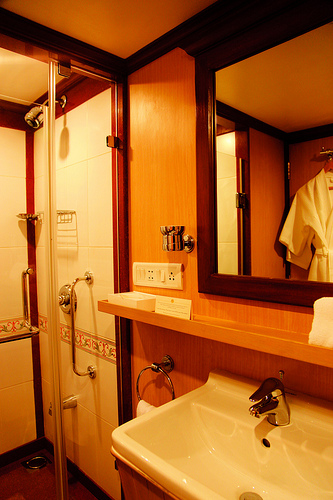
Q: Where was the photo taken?
A: It was taken at the bathroom.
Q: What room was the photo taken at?
A: It was taken at the bathroom.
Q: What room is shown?
A: It is a bathroom.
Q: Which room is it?
A: It is a bathroom.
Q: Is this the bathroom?
A: Yes, it is the bathroom.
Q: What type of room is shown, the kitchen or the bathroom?
A: It is the bathroom.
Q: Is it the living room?
A: No, it is the bathroom.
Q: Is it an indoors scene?
A: Yes, it is indoors.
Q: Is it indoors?
A: Yes, it is indoors.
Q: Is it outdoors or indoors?
A: It is indoors.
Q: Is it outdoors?
A: No, it is indoors.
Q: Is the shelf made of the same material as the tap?
A: No, the shelf is made of wood and the tap is made of metal.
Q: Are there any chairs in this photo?
A: No, there are no chairs.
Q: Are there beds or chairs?
A: No, there are no chairs or beds.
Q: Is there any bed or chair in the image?
A: No, there are no chairs or beds.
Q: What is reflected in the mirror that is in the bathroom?
A: The robe is reflected in the mirror.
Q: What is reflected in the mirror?
A: The robe is reflected in the mirror.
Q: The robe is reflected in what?
A: The robe is reflected in the mirror.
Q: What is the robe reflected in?
A: The robe is reflected in the mirror.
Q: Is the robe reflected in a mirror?
A: Yes, the robe is reflected in a mirror.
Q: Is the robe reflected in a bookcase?
A: No, the robe is reflected in a mirror.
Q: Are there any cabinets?
A: No, there are no cabinets.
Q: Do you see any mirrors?
A: Yes, there is a mirror.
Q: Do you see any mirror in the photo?
A: Yes, there is a mirror.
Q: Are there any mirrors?
A: Yes, there is a mirror.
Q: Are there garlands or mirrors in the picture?
A: Yes, there is a mirror.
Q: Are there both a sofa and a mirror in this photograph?
A: No, there is a mirror but no sofas.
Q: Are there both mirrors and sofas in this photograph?
A: No, there is a mirror but no sofas.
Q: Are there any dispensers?
A: No, there are no dispensers.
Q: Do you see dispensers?
A: No, there are no dispensers.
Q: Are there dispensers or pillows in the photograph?
A: No, there are no dispensers or pillows.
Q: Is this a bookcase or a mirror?
A: This is a mirror.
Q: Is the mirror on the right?
A: Yes, the mirror is on the right of the image.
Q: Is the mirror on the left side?
A: No, the mirror is on the right of the image.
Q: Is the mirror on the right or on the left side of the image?
A: The mirror is on the right of the image.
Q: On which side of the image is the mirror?
A: The mirror is on the right of the image.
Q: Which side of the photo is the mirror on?
A: The mirror is on the right of the image.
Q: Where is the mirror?
A: The mirror is in the bathroom.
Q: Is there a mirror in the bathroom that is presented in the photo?
A: Yes, there is a mirror in the bathroom.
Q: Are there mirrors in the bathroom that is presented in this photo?
A: Yes, there is a mirror in the bathroom.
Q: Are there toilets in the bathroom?
A: No, there is a mirror in the bathroom.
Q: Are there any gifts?
A: No, there are no gifts.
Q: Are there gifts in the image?
A: No, there are no gifts.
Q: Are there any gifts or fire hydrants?
A: No, there are no gifts or fire hydrants.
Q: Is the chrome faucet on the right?
A: Yes, the faucet is on the right of the image.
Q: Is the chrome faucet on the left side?
A: No, the tap is on the right of the image.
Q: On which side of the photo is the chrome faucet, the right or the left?
A: The faucet is on the right of the image.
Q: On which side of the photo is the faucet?
A: The faucet is on the right of the image.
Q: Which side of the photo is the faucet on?
A: The faucet is on the right of the image.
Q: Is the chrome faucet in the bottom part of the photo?
A: Yes, the faucet is in the bottom of the image.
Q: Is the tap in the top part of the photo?
A: No, the tap is in the bottom of the image.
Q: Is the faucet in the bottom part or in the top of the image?
A: The faucet is in the bottom of the image.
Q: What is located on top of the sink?
A: The tap is on top of the sink.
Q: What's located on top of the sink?
A: The tap is on top of the sink.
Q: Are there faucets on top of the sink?
A: Yes, there is a faucet on top of the sink.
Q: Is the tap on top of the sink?
A: Yes, the tap is on top of the sink.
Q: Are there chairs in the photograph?
A: No, there are no chairs.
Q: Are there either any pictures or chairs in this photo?
A: No, there are no chairs or pictures.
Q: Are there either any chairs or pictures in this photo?
A: No, there are no chairs or pictures.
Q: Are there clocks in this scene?
A: No, there are no clocks.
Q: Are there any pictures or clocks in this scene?
A: No, there are no clocks or pictures.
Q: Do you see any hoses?
A: No, there are no hoses.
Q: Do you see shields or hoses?
A: No, there are no hoses or shields.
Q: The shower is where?
A: The shower is in the bathroom.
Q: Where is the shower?
A: The shower is in the bathroom.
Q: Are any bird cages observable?
A: No, there are no bird cages.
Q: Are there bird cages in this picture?
A: No, there are no bird cages.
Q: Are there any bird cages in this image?
A: No, there are no bird cages.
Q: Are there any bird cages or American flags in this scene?
A: No, there are no bird cages or American flags.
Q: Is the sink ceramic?
A: Yes, the sink is ceramic.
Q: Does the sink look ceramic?
A: Yes, the sink is ceramic.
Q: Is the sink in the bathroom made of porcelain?
A: Yes, the sink is made of porcelain.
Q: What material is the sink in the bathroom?
A: The sink is made of porcelain.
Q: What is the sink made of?
A: The sink is made of porcelain.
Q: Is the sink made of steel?
A: No, the sink is made of porcelain.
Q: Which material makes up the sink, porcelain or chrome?
A: The sink is made of porcelain.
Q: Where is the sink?
A: The sink is in the bathroom.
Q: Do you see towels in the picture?
A: Yes, there is a towel.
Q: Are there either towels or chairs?
A: Yes, there is a towel.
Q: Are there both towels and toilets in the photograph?
A: No, there is a towel but no toilets.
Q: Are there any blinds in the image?
A: No, there are no blinds.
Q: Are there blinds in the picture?
A: No, there are no blinds.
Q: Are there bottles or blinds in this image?
A: No, there are no blinds or bottles.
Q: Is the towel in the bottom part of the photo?
A: Yes, the towel is in the bottom of the image.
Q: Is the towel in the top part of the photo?
A: No, the towel is in the bottom of the image.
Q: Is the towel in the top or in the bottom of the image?
A: The towel is in the bottom of the image.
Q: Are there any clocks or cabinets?
A: No, there are no cabinets or clocks.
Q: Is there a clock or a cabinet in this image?
A: No, there are no cabinets or clocks.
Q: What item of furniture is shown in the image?
A: The piece of furniture is a shelf.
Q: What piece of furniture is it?
A: The piece of furniture is a shelf.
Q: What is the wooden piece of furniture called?
A: The piece of furniture is a shelf.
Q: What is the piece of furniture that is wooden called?
A: The piece of furniture is a shelf.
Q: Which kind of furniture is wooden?
A: The furniture is a shelf.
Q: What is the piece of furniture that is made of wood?
A: The piece of furniture is a shelf.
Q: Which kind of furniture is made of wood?
A: The furniture is a shelf.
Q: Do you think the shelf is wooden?
A: Yes, the shelf is wooden.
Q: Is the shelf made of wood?
A: Yes, the shelf is made of wood.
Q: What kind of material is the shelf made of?
A: The shelf is made of wood.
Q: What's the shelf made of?
A: The shelf is made of wood.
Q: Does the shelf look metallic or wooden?
A: The shelf is wooden.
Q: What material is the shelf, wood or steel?
A: The shelf is made of wood.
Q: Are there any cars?
A: No, there are no cars.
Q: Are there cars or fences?
A: No, there are no cars or fences.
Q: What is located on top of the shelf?
A: The sign is on top of the shelf.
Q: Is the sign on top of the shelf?
A: Yes, the sign is on top of the shelf.